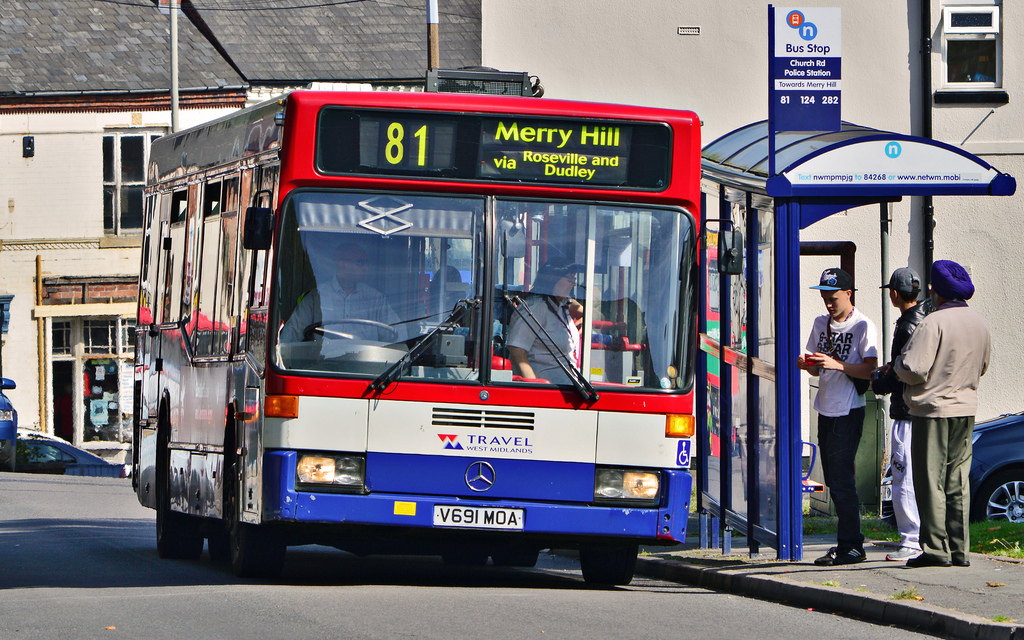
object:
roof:
[227, 27, 249, 43]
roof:
[336, 38, 353, 50]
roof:
[88, 48, 105, 65]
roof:
[375, 19, 399, 39]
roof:
[113, 39, 135, 53]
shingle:
[131, 93, 249, 111]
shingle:
[0, 93, 299, 114]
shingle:
[71, 24, 156, 117]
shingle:
[250, 43, 447, 85]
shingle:
[20, 13, 77, 78]